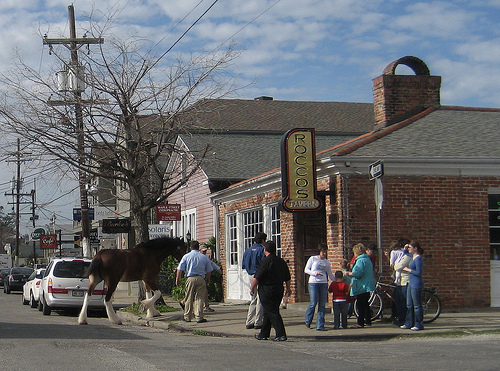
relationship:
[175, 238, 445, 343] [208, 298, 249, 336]
people at sidewalk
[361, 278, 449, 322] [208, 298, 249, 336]
bike at sidewalk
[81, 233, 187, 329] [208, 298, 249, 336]
horse at sidewalk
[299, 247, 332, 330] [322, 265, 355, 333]
woman with kid